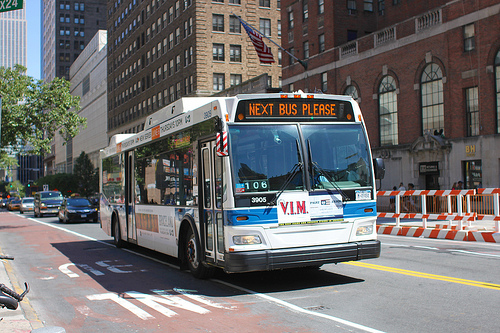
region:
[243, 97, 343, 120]
top of bus has letters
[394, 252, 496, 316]
road has yellow street marks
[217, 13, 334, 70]
americna flag is hanging from building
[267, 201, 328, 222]
there are letters in front of bus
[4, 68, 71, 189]
the tree has lots of leaves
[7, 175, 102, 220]
there are cars behind the bus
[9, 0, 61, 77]
the sky is shiny and blue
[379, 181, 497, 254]
the street has a red border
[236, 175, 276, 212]
bus has numbers on it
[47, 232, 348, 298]
the bus has a shadow on floor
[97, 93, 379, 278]
Bus on the street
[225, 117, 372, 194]
Bus windshield made of glass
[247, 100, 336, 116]
The text is orange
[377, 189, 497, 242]
White and orange barrier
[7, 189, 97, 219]
Vehicles behind the bus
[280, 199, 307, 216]
The bus says V.I.M.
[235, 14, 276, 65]
American flag hanging down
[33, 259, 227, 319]
White text on street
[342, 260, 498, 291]
The lines are yellow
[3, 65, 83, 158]
Green leaves on the tree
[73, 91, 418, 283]
the bus is white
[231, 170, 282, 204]
the number is 106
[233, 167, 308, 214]
the number is 106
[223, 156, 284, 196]
the number is 106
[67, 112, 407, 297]
A bus on the street.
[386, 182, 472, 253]
Orange and white barriers on the road.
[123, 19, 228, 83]
Windows on the building.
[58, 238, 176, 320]
White letters on the street.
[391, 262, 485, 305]
Double yellow line in the road.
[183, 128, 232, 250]
The door to get on the bus.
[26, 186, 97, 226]
Cars behind the bus.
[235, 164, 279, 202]
A number on the bus.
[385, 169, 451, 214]
People walking on the sidewalk.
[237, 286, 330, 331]
A white line on the sidewalk.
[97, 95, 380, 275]
Bus paint is blue and white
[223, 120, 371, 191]
Windshield made of glass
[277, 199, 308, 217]
A sign that says V.I.M.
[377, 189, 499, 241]
Orange and white barrier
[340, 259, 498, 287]
Yellow lines on street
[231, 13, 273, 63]
American flag is hanging down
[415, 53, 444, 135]
Large window on building